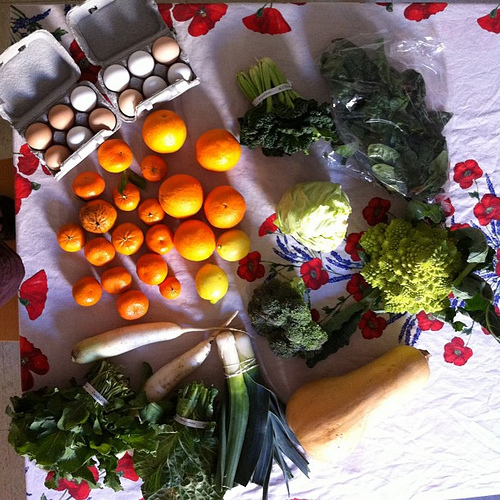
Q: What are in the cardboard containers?
A: Eggs.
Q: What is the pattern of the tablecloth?
A: Floral.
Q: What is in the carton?
A: Eggs.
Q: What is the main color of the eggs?
A: Brown and white.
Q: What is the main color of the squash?
A: ORange.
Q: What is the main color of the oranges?
A: Orange.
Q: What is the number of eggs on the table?
A: 12.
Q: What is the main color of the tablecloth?
A: White.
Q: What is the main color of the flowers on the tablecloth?
A: Red.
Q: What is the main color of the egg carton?
A: Grey.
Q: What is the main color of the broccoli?
A: Green.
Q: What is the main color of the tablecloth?
A: White.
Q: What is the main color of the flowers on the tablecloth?
A: Red.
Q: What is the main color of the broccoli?
A: Green.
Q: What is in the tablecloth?
A: Wrinkles.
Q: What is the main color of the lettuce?
A: Green.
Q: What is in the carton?
A: Eggs.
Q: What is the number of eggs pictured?
A: 12.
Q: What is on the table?
A: Healthy foods.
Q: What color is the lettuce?
A: Green.